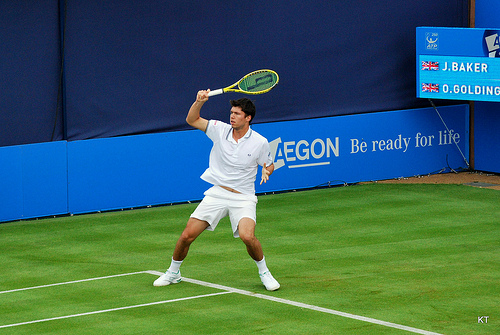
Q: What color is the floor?
A: Green.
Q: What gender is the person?
A: Male.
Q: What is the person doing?
A: Playing tennis.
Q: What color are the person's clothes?
A: White.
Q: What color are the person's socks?
A: White.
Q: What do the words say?
A: Be ready for life.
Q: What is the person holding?
A: A racket.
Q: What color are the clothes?
A: White.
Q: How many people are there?
A: One.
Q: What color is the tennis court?
A: Green.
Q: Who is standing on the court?
A: A man.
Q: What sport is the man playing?
A: Tennis.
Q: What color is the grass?
A: Green.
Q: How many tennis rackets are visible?
A: One.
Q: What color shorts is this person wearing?
A: White.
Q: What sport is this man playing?
A: Tennis.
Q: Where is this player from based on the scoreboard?
A: UK.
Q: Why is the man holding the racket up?
A: To hit the tennis ball.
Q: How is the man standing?
A: With his legs apart.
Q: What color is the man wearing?
A: White.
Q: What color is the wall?
A: Blue.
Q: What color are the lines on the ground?
A: White.